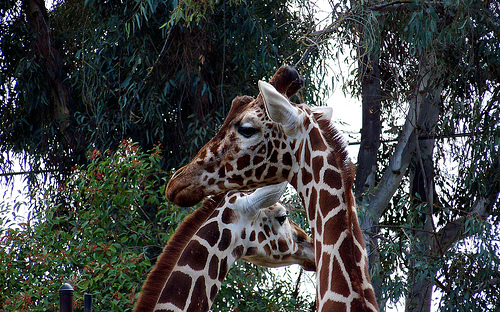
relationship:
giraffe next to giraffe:
[131, 180, 317, 309] [162, 64, 383, 311]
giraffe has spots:
[173, 97, 380, 310] [170, 216, 240, 308]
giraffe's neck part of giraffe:
[135, 226, 235, 312] [131, 180, 317, 309]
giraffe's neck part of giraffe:
[290, 152, 382, 312] [162, 64, 383, 311]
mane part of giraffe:
[320, 115, 366, 242] [162, 64, 383, 311]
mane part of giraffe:
[133, 192, 220, 309] [131, 180, 317, 309]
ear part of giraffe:
[238, 185, 298, 216] [191, 79, 308, 286]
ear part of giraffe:
[256, 78, 295, 127] [154, 81, 354, 310]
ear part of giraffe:
[314, 100, 345, 127] [162, 64, 383, 311]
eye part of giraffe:
[271, 201, 298, 232] [138, 171, 313, 309]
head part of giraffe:
[151, 69, 354, 206] [162, 64, 383, 311]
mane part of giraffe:
[313, 114, 356, 201] [162, 64, 383, 311]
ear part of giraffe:
[259, 80, 297, 124] [162, 64, 383, 311]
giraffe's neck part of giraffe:
[290, 152, 391, 309] [162, 64, 383, 311]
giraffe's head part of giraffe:
[176, 74, 316, 268] [162, 64, 383, 311]